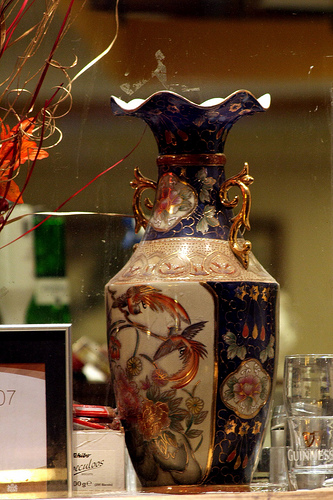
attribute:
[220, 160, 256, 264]
handle — gold , on the vase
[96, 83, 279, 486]
vase — antique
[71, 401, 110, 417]
wrapper — next to vase, red 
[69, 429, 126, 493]
box — white , cardboard 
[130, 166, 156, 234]
accent — gold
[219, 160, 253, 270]
accent — gold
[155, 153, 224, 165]
accent — gold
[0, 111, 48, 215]
flower — decorative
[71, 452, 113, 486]
writing — on the box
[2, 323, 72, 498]
picture — framed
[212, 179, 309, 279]
handle — gold 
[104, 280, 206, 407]
birds — playful, flying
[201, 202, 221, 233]
leaves — gold, green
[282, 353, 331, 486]
bottle — green , in background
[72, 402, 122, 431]
candybars — on top of the box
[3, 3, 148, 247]
material — red, gold, decorative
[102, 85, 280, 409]
puppy — gold 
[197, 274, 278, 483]
panel — dark blue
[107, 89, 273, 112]
mouth — of the vase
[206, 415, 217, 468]
stripe —  on the vase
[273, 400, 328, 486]
glass — on the table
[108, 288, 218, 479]
flower — on the vase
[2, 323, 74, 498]
frame — silver